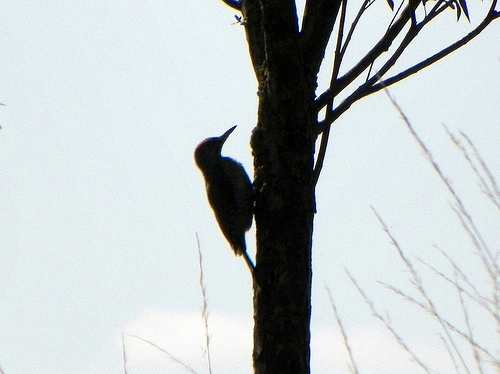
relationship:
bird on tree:
[193, 124, 268, 257] [223, 0, 499, 372]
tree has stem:
[223, 0, 499, 372] [314, 1, 366, 186]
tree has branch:
[223, 0, 499, 372] [319, 1, 464, 135]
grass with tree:
[119, 71, 498, 373] [223, 0, 499, 372]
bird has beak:
[193, 124, 268, 257] [219, 124, 238, 144]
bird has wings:
[193, 124, 268, 257] [206, 180, 249, 259]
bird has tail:
[193, 124, 268, 257] [227, 238, 249, 257]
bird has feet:
[193, 124, 268, 257] [251, 174, 265, 218]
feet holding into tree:
[251, 174, 265, 218] [223, 0, 499, 372]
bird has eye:
[193, 124, 268, 257] [215, 144, 223, 158]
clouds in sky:
[115, 301, 466, 373] [2, 2, 499, 373]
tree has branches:
[223, 0, 499, 372] [225, 1, 500, 177]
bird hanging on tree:
[193, 124, 268, 257] [223, 0, 499, 372]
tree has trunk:
[223, 0, 499, 372] [253, 180, 315, 373]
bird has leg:
[193, 124, 268, 257] [249, 180, 259, 189]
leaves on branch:
[386, 0, 471, 24] [319, 1, 464, 135]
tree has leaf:
[223, 0, 499, 372] [387, 0, 398, 12]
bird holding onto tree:
[193, 124, 268, 257] [223, 0, 499, 372]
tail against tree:
[227, 238, 249, 257] [223, 0, 499, 372]